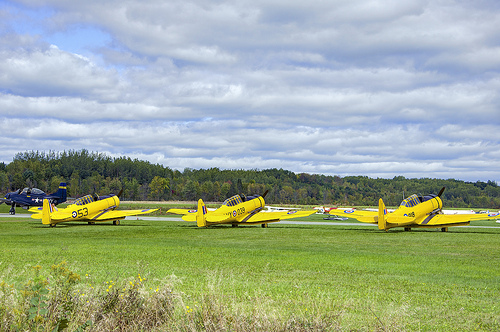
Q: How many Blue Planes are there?
A: 1.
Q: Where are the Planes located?
A: On a Field.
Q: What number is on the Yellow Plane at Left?
A: 53.